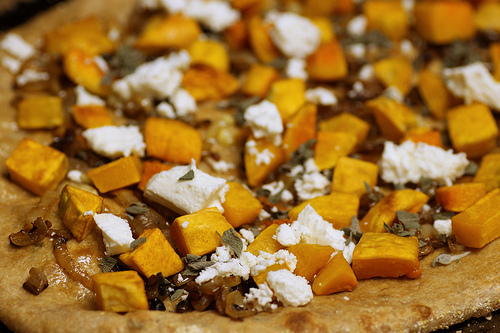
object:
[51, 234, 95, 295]
onion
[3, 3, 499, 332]
pita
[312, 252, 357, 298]
cheese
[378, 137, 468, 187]
cheese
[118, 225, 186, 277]
potato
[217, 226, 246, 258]
spice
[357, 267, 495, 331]
edge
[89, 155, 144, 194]
carrot